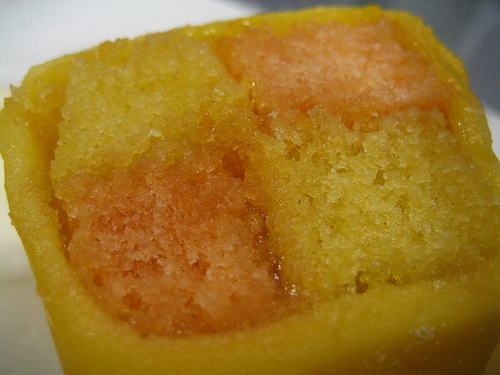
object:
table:
[1, 0, 498, 374]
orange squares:
[48, 4, 499, 336]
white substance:
[409, 323, 440, 362]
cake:
[1, 0, 500, 375]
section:
[268, 0, 500, 370]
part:
[214, 12, 451, 111]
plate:
[0, 0, 500, 375]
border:
[1, 129, 149, 375]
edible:
[235, 105, 497, 297]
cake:
[46, 40, 257, 213]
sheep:
[41, 29, 500, 323]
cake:
[52, 133, 298, 336]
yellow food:
[0, 6, 500, 373]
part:
[238, 105, 500, 306]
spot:
[127, 183, 252, 289]